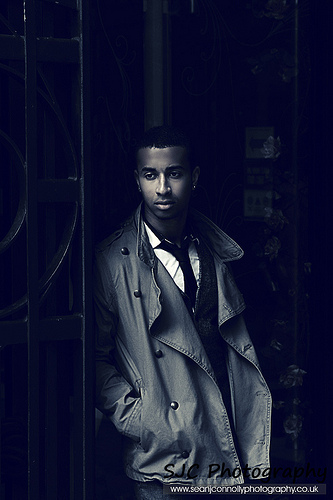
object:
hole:
[244, 343, 251, 351]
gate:
[1, 0, 88, 499]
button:
[170, 402, 181, 411]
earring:
[193, 185, 196, 189]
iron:
[15, 69, 76, 211]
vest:
[162, 232, 232, 423]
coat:
[96, 203, 273, 486]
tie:
[152, 234, 202, 309]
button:
[120, 246, 129, 255]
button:
[134, 289, 142, 298]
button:
[155, 349, 163, 360]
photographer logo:
[164, 462, 328, 481]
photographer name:
[170, 486, 319, 494]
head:
[133, 123, 200, 219]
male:
[93, 106, 276, 498]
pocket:
[137, 397, 155, 453]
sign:
[232, 115, 295, 223]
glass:
[205, 64, 298, 236]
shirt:
[144, 223, 200, 296]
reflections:
[234, 105, 297, 291]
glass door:
[196, 12, 332, 499]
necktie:
[160, 240, 199, 312]